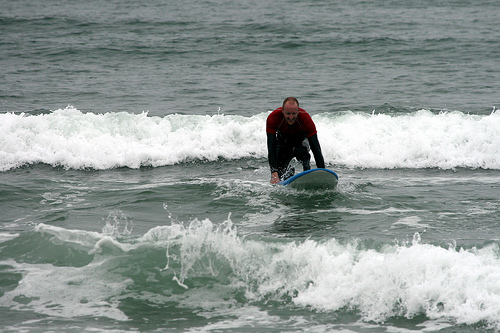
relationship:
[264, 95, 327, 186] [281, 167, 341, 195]
man kneeling on surfboard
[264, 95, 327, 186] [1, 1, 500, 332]
man surfing in water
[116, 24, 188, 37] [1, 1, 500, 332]
ripple in water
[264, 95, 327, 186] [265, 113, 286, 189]
man has right arm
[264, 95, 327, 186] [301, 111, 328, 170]
man has left arm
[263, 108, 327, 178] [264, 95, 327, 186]
wetsuit worn on man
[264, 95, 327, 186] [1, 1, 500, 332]
man surfing on water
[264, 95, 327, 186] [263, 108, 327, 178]
man wearing wetsuit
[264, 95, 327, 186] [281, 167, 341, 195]
man trying to stand on surfboard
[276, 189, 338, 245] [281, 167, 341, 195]
shadow from surfboard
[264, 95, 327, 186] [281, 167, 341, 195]
man standing on surfboard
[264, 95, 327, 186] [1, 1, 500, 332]
man in water